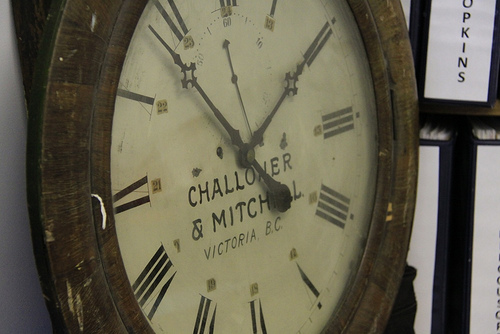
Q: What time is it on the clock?
A: 2:55.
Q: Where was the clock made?
A: Challower & mitchell.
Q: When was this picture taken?
A: During the day.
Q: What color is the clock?
A: Dark brown.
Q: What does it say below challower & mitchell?
A: Victoria B.C.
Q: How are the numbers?
A: Roman numeral.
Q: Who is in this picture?
A: Nobody.